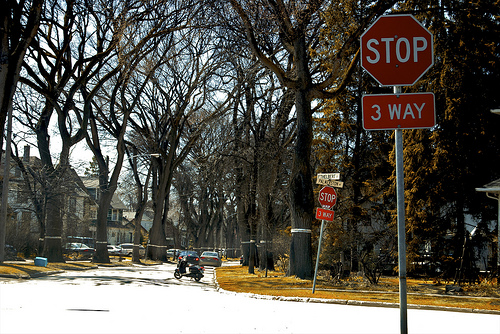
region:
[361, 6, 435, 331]
stop sign with post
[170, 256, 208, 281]
a scooter parked in the road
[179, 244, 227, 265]
two car is running on the road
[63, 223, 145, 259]
some cars parked in the parking area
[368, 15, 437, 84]
a white color text written in the red color stop board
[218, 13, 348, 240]
big trees with its branches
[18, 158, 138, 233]
buildings behind the tree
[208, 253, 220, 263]
indicator of the car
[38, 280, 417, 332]
3 way roads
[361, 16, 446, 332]
metal post with bolt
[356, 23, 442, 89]
stop sign on top right of picture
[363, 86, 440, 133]
sign on pole under stop sign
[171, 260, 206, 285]
motorcycle parked on right side of road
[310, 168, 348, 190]
street sign on pole above stop sign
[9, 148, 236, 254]
houses on left side of street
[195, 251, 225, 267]
car parked on right side of road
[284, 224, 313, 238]
white band on tree on right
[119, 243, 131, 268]
mailbox on left side of road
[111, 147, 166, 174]
street light on left side of road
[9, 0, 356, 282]
large trees along both sides of road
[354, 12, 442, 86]
a red and white stop sign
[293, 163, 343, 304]
a second stop sign with street signs on top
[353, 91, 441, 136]
a red and white sign that says 3 way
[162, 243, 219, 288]
a motorcycle parked at the curb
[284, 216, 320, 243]
a white band around a tree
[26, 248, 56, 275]
a blue box on the grass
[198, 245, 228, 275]
a car parked at the curb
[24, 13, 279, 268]
lots of trees with no leaves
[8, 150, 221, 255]
a row of houses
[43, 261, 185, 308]
shadow of tree on the ground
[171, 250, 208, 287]
a motor scooter is parked curbsiide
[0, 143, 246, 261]
the homes are large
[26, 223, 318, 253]
many of the trees have rings on the trunks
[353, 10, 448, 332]
a stop sign indicating a 3 way stop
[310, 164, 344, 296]
this stop sign has the street name signs on top of it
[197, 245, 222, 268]
this car is parked curbside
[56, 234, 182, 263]
these cars are parked in driveways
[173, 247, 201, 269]
this car is not parked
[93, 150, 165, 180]
the streetlight is not lit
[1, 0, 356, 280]
the lack of leaves on the trees indicate it is late fall or winter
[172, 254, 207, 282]
A black motorcycle in the middle of the street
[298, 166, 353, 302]
A signpost with many signs on it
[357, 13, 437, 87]
The stop sign is red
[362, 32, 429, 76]
The red sign says "Stop"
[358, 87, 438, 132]
The rectangular red sign says 3 way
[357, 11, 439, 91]
The stop sign is shaped like an octagon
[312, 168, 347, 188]
Two small white street signs by the stop sign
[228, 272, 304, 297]
Golden grass grows on the ground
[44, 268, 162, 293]
Shadow of a tree in the road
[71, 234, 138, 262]
Cars parked in front of the building